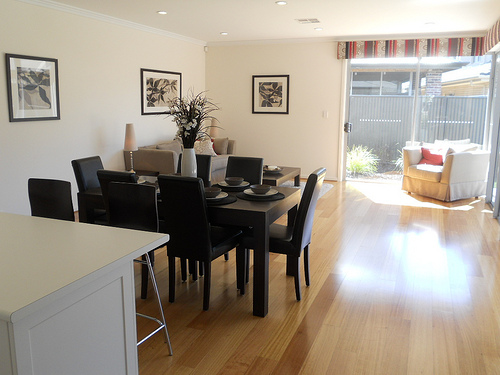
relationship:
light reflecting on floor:
[331, 220, 478, 309] [49, 171, 498, 374]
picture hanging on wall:
[251, 73, 292, 118] [204, 45, 346, 187]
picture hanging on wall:
[138, 65, 184, 116] [2, 1, 207, 219]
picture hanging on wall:
[4, 52, 63, 124] [2, 1, 207, 219]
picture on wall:
[251, 73, 292, 118] [204, 45, 346, 187]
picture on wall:
[138, 65, 184, 116] [2, 1, 207, 219]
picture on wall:
[4, 52, 63, 124] [2, 1, 207, 219]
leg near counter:
[145, 253, 178, 361] [1, 208, 177, 334]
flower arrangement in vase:
[159, 85, 219, 153] [180, 148, 204, 181]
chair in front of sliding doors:
[400, 136, 491, 205] [342, 60, 492, 182]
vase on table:
[180, 148, 204, 181] [73, 170, 304, 325]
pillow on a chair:
[418, 142, 448, 168] [400, 136, 491, 205]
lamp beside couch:
[122, 120, 140, 176] [129, 127, 238, 177]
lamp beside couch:
[210, 116, 220, 139] [129, 127, 238, 177]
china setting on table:
[242, 183, 280, 197] [73, 170, 304, 325]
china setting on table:
[216, 175, 249, 190] [73, 170, 304, 325]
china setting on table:
[199, 184, 229, 200] [73, 170, 304, 325]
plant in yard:
[345, 143, 378, 176] [346, 145, 483, 183]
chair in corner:
[400, 136, 491, 205] [399, 172, 499, 215]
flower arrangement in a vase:
[159, 85, 219, 153] [180, 148, 204, 181]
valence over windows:
[331, 15, 500, 63] [342, 60, 492, 182]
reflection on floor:
[331, 220, 478, 309] [49, 171, 498, 374]